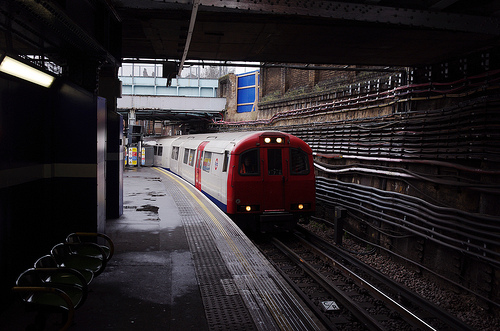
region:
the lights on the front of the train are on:
[222, 115, 333, 251]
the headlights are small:
[228, 195, 315, 225]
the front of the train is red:
[209, 122, 333, 228]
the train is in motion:
[83, 101, 405, 303]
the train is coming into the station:
[97, 105, 322, 225]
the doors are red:
[185, 131, 210, 186]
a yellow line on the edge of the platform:
[150, 155, 230, 242]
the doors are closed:
[187, 135, 208, 190]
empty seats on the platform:
[12, 221, 140, 306]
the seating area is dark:
[0, 127, 274, 321]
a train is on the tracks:
[144, 133, 316, 226]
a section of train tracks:
[258, 221, 473, 329]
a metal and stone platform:
[125, 165, 304, 330]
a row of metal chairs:
[16, 233, 111, 311]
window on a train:
[237, 145, 257, 173]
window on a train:
[266, 146, 280, 173]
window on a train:
[290, 146, 309, 177]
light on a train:
[245, 203, 252, 213]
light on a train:
[296, 201, 303, 208]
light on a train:
[264, 136, 271, 144]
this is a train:
[247, 126, 400, 320]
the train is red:
[175, 163, 319, 188]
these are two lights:
[192, 133, 302, 140]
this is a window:
[205, 130, 271, 155]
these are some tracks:
[226, 265, 356, 295]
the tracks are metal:
[302, 245, 342, 296]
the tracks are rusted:
[300, 218, 400, 315]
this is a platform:
[145, 265, 190, 326]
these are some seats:
[32, 217, 138, 322]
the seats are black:
[14, 253, 79, 315]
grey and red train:
[143, 129, 316, 228]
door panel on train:
[194, 147, 202, 188]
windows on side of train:
[181, 147, 196, 166]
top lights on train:
[263, 133, 283, 146]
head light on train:
[244, 206, 251, 211]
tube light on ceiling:
[3, 57, 55, 91]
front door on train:
[263, 145, 286, 213]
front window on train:
[288, 147, 308, 178]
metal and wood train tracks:
[279, 230, 437, 330]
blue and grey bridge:
[117, 60, 229, 114]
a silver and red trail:
[133, 125, 344, 231]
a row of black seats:
[13, 214, 111, 328]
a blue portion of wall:
[227, 74, 274, 119]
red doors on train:
[185, 131, 222, 199]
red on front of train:
[216, 114, 359, 248]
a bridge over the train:
[124, 70, 243, 130]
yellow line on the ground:
[153, 155, 288, 330]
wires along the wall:
[255, 87, 499, 284]